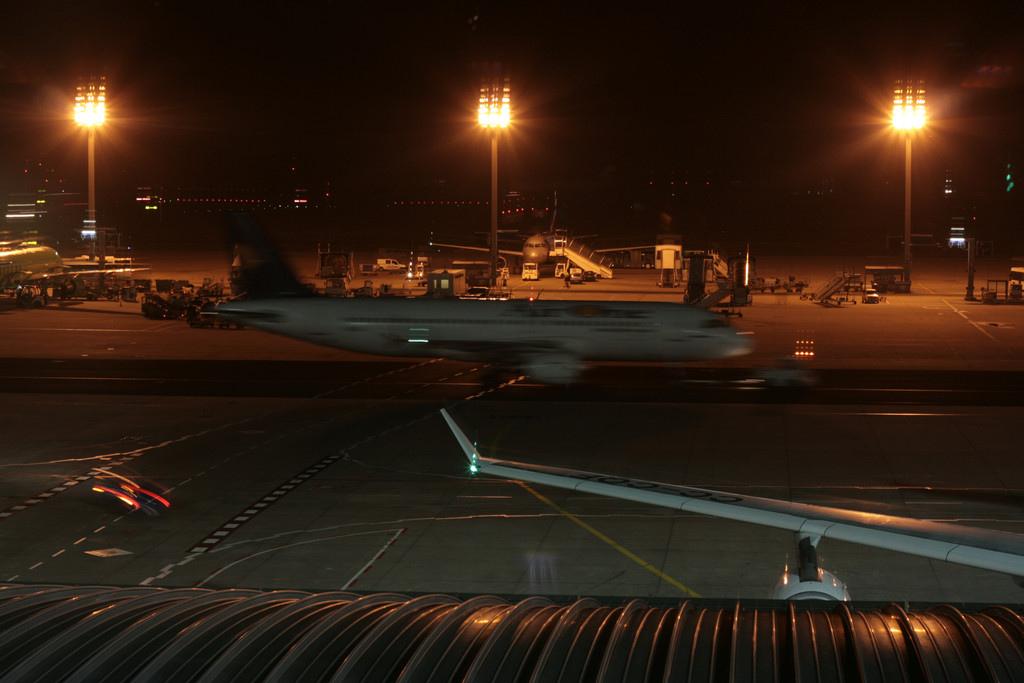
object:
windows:
[424, 316, 445, 326]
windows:
[387, 317, 400, 323]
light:
[465, 78, 522, 143]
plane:
[186, 273, 772, 431]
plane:
[131, 163, 782, 445]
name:
[495, 296, 661, 323]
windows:
[448, 316, 475, 324]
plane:
[205, 225, 865, 437]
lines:
[185, 536, 229, 547]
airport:
[0, 40, 1023, 682]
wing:
[402, 385, 1018, 619]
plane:
[373, 376, 953, 675]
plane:
[183, 257, 763, 418]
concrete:
[153, 357, 533, 615]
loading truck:
[27, 245, 148, 313]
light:
[991, 162, 1023, 208]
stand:
[52, 463, 232, 563]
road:
[13, 459, 531, 630]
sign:
[943, 223, 972, 251]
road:
[810, 253, 1016, 409]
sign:
[130, 185, 163, 215]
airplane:
[183, 214, 758, 397]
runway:
[132, 337, 950, 670]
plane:
[388, 374, 1020, 660]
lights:
[71, 74, 115, 131]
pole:
[76, 98, 104, 272]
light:
[468, 62, 522, 134]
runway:
[326, 253, 643, 314]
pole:
[484, 80, 506, 291]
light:
[885, 80, 932, 139]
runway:
[800, 284, 1017, 513]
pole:
[894, 136, 921, 290]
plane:
[462, 215, 705, 274]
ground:
[90, 245, 986, 339]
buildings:
[121, 154, 346, 224]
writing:
[496, 301, 657, 324]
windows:
[358, 316, 371, 323]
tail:
[195, 219, 326, 297]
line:
[493, 459, 735, 598]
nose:
[729, 333, 757, 365]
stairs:
[558, 243, 616, 280]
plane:
[487, 204, 561, 271]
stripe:
[499, 444, 713, 592]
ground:
[19, 250, 1019, 603]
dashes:
[179, 546, 220, 557]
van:
[372, 256, 408, 271]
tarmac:
[17, 253, 1021, 597]